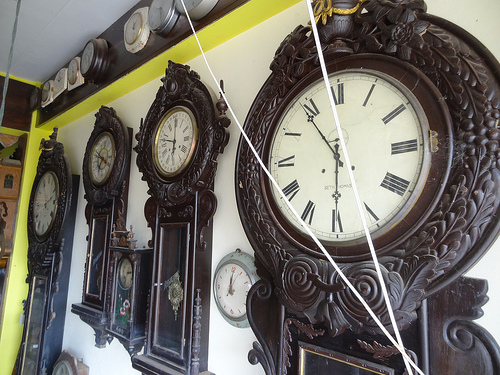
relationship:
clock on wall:
[144, 1, 184, 39] [50, 1, 499, 375]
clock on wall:
[120, 3, 154, 55] [50, 1, 499, 375]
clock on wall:
[76, 36, 113, 83] [50, 1, 499, 375]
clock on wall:
[62, 55, 87, 93] [50, 1, 499, 375]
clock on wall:
[232, 1, 498, 375] [50, 1, 499, 375]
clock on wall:
[127, 54, 235, 375] [50, 1, 499, 375]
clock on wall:
[69, 99, 139, 352] [50, 1, 499, 375]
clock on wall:
[12, 122, 85, 375] [50, 1, 499, 375]